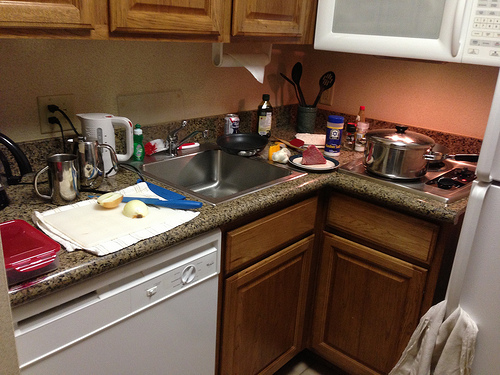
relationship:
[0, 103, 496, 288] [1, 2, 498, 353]
countertop in kitchen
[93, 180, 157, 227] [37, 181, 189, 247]
onion on towle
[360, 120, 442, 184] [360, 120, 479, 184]
pot on pot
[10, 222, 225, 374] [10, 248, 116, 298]
dish washer under counter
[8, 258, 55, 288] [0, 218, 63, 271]
bowl has lid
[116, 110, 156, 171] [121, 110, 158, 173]
soap in bottle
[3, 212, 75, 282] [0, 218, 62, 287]
lid over bowl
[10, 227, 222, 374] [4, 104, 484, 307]
dish washer underneath counter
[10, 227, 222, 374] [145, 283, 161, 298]
dish washer has switch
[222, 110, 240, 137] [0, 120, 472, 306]
soda can sitting on counter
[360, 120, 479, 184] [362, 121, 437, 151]
pot has lid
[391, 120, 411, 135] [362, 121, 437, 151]
knob on lid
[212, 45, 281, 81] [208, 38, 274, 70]
paper towel on roll